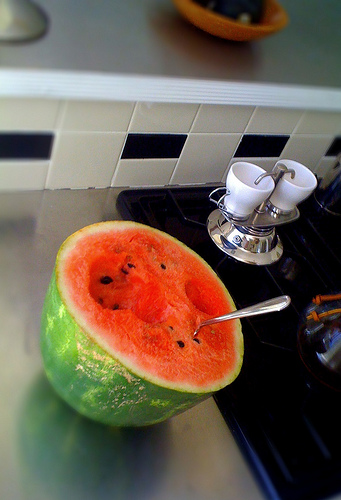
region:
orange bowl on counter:
[164, 0, 307, 47]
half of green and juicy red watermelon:
[48, 215, 258, 425]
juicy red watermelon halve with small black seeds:
[92, 251, 203, 315]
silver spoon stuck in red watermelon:
[188, 286, 293, 333]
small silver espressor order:
[208, 197, 297, 258]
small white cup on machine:
[223, 160, 276, 206]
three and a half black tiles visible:
[0, 6, 336, 98]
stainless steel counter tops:
[0, 186, 289, 487]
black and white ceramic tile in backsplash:
[0, 106, 340, 179]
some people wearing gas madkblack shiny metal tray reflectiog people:
[41, 245, 246, 428]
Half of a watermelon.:
[36, 218, 244, 426]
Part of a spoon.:
[192, 294, 291, 335]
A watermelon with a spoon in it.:
[39, 219, 290, 427]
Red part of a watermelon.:
[64, 225, 236, 387]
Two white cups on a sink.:
[223, 158, 318, 218]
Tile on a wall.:
[0, 95, 339, 192]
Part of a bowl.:
[172, 1, 287, 41]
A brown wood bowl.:
[172, 0, 289, 44]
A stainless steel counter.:
[1, 189, 265, 498]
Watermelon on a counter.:
[38, 217, 245, 426]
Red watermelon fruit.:
[67, 228, 235, 385]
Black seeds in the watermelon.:
[95, 257, 216, 348]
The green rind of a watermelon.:
[39, 218, 242, 426]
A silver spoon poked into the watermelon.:
[186, 293, 293, 336]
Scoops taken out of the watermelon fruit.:
[89, 258, 161, 322]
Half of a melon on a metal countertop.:
[0, 187, 288, 497]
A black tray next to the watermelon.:
[112, 183, 338, 496]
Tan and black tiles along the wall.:
[0, 94, 339, 185]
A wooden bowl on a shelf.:
[177, 2, 290, 40]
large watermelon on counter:
[41, 190, 258, 472]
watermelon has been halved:
[60, 216, 189, 433]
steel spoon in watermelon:
[194, 280, 286, 339]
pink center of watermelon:
[19, 172, 239, 422]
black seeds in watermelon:
[110, 235, 212, 373]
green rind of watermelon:
[47, 278, 169, 450]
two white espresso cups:
[222, 144, 316, 226]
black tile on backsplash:
[16, 123, 338, 183]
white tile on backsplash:
[7, 123, 326, 202]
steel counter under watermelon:
[3, 219, 203, 498]